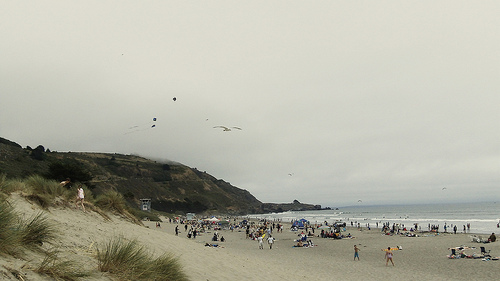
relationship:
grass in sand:
[120, 240, 172, 278] [26, 207, 484, 277]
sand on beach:
[1, 194, 498, 277] [201, 197, 498, 279]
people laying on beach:
[441, 219, 499, 265] [254, 210, 432, 277]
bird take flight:
[208, 123, 250, 133] [185, 100, 254, 144]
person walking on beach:
[381, 245, 403, 267] [247, 210, 499, 277]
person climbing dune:
[381, 245, 398, 266] [14, 170, 220, 279]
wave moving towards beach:
[259, 213, 499, 226] [130, 204, 498, 274]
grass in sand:
[22, 213, 58, 250] [52, 217, 148, 237]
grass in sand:
[34, 248, 91, 277] [3, 172, 230, 279]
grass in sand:
[23, 173, 82, 203] [38, 194, 93, 230]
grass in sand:
[18, 180, 131, 210] [68, 218, 166, 241]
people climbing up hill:
[65, 177, 88, 208] [67, 200, 149, 241]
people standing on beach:
[172, 227, 198, 239] [156, 209, 498, 279]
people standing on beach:
[257, 235, 265, 251] [167, 223, 234, 249]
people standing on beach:
[222, 213, 273, 253] [161, 186, 497, 273]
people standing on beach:
[257, 235, 265, 251] [136, 206, 499, 280]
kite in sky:
[171, 96, 181, 102] [31, 16, 486, 150]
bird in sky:
[204, 107, 246, 138] [51, 5, 491, 148]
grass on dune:
[90, 235, 188, 280] [5, 187, 165, 279]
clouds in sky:
[350, 150, 498, 204] [243, 24, 498, 121]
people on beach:
[257, 235, 265, 251] [156, 209, 498, 279]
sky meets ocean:
[386, 187, 497, 206] [401, 198, 499, 219]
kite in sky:
[171, 96, 181, 102] [0, 0, 498, 210]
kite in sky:
[147, 123, 157, 131] [0, 0, 498, 210]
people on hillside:
[74, 183, 91, 211] [0, 134, 248, 235]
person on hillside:
[381, 245, 398, 266] [0, 134, 248, 235]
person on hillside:
[347, 236, 364, 266] [0, 134, 248, 235]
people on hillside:
[257, 235, 265, 251] [0, 134, 248, 235]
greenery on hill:
[5, 134, 282, 217] [2, 137, 268, 217]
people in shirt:
[74, 183, 91, 211] [76, 185, 86, 201]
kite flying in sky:
[168, 94, 180, 102] [0, 2, 498, 144]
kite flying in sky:
[147, 116, 158, 131] [0, 2, 498, 144]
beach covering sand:
[3, 190, 498, 279] [1, 194, 498, 277]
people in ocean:
[257, 235, 265, 251] [359, 206, 452, 239]